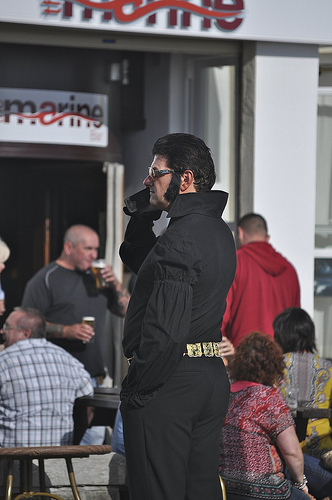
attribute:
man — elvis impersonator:
[110, 126, 242, 497]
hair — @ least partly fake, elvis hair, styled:
[148, 130, 217, 203]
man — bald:
[20, 219, 134, 447]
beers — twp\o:
[75, 256, 109, 349]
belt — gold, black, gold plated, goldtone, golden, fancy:
[126, 339, 223, 376]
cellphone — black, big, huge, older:
[121, 180, 158, 218]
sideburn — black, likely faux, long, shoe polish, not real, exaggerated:
[162, 167, 185, 205]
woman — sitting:
[221, 331, 316, 499]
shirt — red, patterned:
[219, 380, 297, 498]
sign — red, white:
[34, 0, 247, 38]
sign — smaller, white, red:
[3, 87, 112, 151]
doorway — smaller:
[0, 155, 116, 500]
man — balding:
[0, 299, 103, 455]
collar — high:
[161, 187, 231, 227]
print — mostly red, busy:
[224, 386, 292, 494]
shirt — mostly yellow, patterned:
[270, 350, 331, 459]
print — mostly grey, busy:
[278, 350, 331, 451]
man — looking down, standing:
[220, 208, 302, 374]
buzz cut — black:
[234, 213, 272, 243]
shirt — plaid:
[1, 337, 94, 449]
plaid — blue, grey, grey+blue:
[7, 352, 71, 439]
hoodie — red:
[222, 242, 299, 351]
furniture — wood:
[0, 438, 116, 500]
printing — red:
[42, 1, 243, 33]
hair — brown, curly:
[223, 329, 285, 390]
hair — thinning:
[12, 304, 48, 342]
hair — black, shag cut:
[269, 304, 321, 358]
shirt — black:
[112, 187, 239, 408]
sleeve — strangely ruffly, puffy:
[113, 221, 198, 412]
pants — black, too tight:
[120, 353, 236, 500]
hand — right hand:
[66, 322, 97, 340]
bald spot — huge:
[65, 223, 98, 244]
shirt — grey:
[18, 257, 111, 377]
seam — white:
[41, 265, 59, 289]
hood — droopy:
[238, 240, 290, 281]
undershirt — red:
[227, 377, 261, 394]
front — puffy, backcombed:
[151, 132, 187, 158]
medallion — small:
[186, 340, 204, 358]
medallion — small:
[201, 340, 213, 359]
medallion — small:
[212, 339, 221, 359]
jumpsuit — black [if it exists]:
[110, 186, 239, 500]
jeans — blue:
[272, 446, 331, 499]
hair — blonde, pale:
[0, 239, 17, 262]